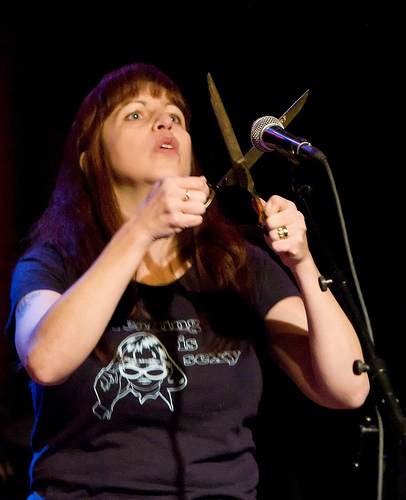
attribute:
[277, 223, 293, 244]
ring — silver 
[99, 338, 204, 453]
girl — line-drawing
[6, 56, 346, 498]
woman — upward-looking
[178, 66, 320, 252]
scissors — open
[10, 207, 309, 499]
shirt — dark blue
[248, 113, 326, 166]
microphone — black , blue 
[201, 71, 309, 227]
scissors — large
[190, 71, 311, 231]
scissors — large 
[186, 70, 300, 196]
shears — metal